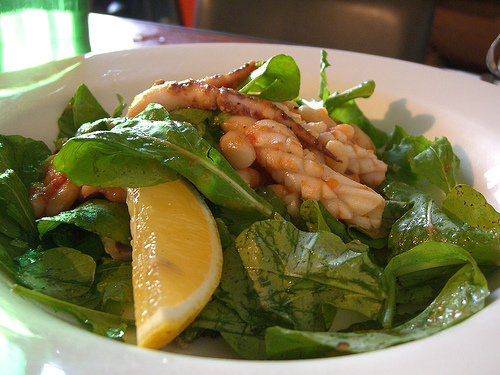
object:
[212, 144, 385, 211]
cooked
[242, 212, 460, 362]
salad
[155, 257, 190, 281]
seed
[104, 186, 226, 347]
lemon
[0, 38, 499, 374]
bowl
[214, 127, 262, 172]
bean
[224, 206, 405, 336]
leaf